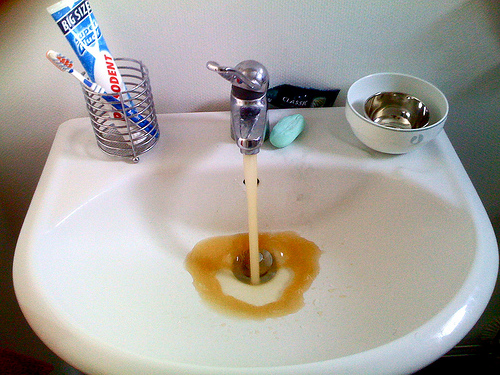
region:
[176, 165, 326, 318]
dirty water coming out of the sink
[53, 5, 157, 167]
toothpaste and brush in a silverholder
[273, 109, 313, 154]
small green bar of soap on sink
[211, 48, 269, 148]
silver faucet on the sink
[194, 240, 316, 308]
dirty water in the sink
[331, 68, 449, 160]
white ceramic bowl on the sink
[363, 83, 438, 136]
metal bowl in the ceramic bowl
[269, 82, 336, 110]
package stuck behind the sink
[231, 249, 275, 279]
drain in the sink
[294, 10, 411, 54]
wall behind the sink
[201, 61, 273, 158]
silver faucet on sink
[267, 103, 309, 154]
bar of green soap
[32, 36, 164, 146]
blue and white toothbrush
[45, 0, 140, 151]
white and blue tube of toothpaste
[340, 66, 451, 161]
white bowl on the sink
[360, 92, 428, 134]
small stainless steel bowl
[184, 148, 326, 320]
brown water in the sink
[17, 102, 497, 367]
white ceramic bathroom sink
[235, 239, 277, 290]
drain in the bottom of the sink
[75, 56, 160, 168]
metal toothbrush caddy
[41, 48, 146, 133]
a toothbrush on a sink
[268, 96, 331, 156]
green soap on a sink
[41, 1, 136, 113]
tooth paste on a sink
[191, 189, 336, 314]
dirty water in a sink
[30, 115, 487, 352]
a bathroom white sink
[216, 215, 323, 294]
a drain in a sink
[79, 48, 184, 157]
a steel holder on a sink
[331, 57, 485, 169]
a bowl on a sink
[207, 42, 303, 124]
a handle on a sink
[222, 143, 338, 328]
Disgusting water running from a faucet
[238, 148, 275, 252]
The water is a gross brown color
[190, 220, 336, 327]
Dirty brown water pooling up in the sink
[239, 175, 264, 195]
A small hole behind the stream of water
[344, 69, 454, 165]
A small white bowl on the edge of the sink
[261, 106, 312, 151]
A small green bar of soap by the sink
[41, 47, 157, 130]
A tooth brush in the metal holder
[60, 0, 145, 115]
A tube of tooth paste in the metal holder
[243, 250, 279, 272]
A grey stopper in the white sink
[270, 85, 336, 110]
A black wrapper behind the sink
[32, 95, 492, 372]
A small white sink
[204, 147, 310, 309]
Brown water running from tap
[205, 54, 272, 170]
Chrome faucet on sink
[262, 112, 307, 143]
A green bar of soap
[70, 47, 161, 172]
A metal toothbrush holder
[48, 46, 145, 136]
A red, white and blue toothbrush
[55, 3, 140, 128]
A red, white and blue tube of toothpaste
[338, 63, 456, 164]
A white dish sitting on sink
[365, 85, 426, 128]
A silver dish sitting in white dish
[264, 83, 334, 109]
A black paper behind faucet